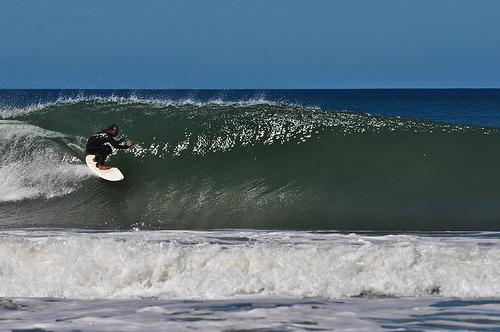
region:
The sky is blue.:
[2, 0, 499, 90]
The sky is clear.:
[2, 0, 499, 97]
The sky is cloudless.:
[0, 0, 497, 101]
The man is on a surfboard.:
[43, 98, 188, 219]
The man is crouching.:
[53, 103, 180, 232]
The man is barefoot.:
[33, 98, 193, 213]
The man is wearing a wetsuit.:
[53, 88, 175, 220]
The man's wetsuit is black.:
[51, 87, 166, 199]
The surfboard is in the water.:
[61, 102, 174, 226]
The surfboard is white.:
[26, 80, 220, 247]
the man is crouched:
[74, 115, 139, 187]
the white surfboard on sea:
[79, 150, 126, 182]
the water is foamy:
[0, 221, 499, 301]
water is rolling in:
[0, 85, 490, 216]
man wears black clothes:
[79, 118, 136, 172]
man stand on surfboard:
[74, 116, 141, 185]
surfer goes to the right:
[73, 113, 144, 190]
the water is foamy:
[3, 294, 496, 330]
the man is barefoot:
[74, 118, 145, 190]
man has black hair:
[79, 116, 139, 175]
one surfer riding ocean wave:
[8, 94, 490, 220]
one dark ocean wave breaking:
[24, 88, 479, 128]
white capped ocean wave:
[6, 94, 306, 121]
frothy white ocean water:
[9, 229, 491, 311]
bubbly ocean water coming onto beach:
[21, 299, 479, 331]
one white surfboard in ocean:
[85, 154, 127, 182]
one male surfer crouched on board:
[82, 124, 141, 185]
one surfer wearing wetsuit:
[82, 120, 134, 170]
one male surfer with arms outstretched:
[83, 124, 141, 182]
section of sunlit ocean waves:
[143, 92, 385, 218]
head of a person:
[103, 120, 128, 140]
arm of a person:
[103, 135, 132, 152]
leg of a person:
[89, 138, 113, 162]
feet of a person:
[89, 160, 127, 172]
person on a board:
[48, 112, 174, 203]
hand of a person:
[125, 134, 137, 147]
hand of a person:
[120, 128, 135, 140]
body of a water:
[328, 152, 465, 212]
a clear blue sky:
[155, 27, 345, 91]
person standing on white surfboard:
[85, 120, 130, 182]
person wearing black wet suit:
[81, 121, 134, 181]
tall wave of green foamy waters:
[11, 93, 401, 231]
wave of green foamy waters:
[0, 227, 497, 304]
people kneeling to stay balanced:
[83, 122, 136, 181]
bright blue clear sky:
[2, 0, 494, 90]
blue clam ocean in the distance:
[292, 87, 497, 124]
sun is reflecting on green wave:
[157, 117, 374, 170]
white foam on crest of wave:
[6, 91, 319, 116]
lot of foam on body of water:
[7, 235, 492, 295]